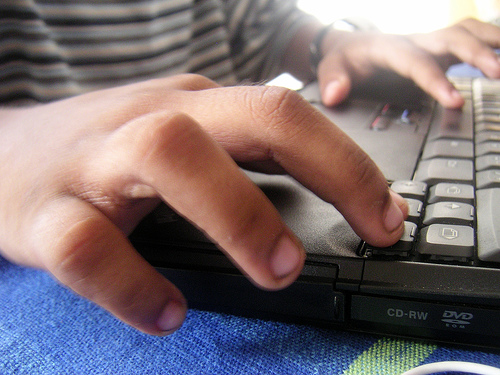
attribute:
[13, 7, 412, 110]
black shirt — is black, is gray, is white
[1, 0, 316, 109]
shirt — is striped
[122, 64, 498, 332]
laptop — black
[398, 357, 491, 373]
cord — white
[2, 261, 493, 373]
tablecloth — is blue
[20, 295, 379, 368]
cloth — blue, green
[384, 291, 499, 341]
lettering — is white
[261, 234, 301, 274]
nails — are tiny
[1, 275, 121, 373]
tablecloth — green, blue, woven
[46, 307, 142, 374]
jeans — are blue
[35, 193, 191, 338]
finger — is short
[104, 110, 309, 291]
finger — is short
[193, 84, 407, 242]
finger — is short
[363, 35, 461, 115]
finger — is short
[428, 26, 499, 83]
finger — is short